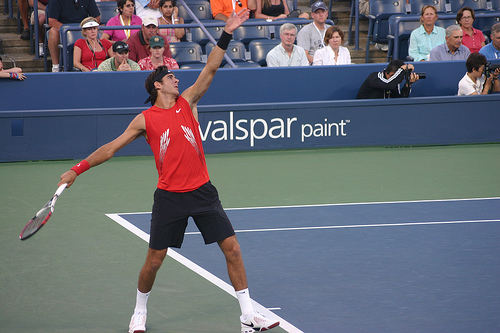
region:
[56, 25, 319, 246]
this is a tennis match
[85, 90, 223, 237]
the tank top is red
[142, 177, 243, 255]
the shorts are black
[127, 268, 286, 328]
the shoes are white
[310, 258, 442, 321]
the court is blue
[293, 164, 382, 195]
the court is green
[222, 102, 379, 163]
this is an advertisement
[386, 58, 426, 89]
a man with a camera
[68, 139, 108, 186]
a red arm band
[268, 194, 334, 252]
white lines on the court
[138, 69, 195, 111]
a man wearing a hat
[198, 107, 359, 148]
letters on the wall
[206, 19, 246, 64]
a black arm band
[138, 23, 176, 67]
a woman wearing a hat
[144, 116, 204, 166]
a picture on the shirt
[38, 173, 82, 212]
a handle on the racket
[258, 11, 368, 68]
people watching the game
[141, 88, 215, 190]
man wearing red tank top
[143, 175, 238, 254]
black shorts on tennis player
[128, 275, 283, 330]
white socks and white tennis shoes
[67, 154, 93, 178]
red sweatbands on man's wrists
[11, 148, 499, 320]
blue and green tennis court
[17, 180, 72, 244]
white black and red tennis racket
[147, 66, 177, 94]
black sweatband on man's head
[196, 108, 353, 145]
white letters showing sponsor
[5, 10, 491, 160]
blue stands filled with spectators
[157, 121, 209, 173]
white Nike design onb famous tennis player Rafael Nadal's shirt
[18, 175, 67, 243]
man is holding a tennis racket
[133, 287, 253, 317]
man is wearing white socks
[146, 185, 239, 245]
man is wearing black shorts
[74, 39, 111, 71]
woman is wearing a red shirt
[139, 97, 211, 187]
man is wearing a red shirt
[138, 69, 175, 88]
man is wearing a black head band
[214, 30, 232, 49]
man wearing a black wrist band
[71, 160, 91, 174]
man is wearing a red wrist band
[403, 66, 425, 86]
man holding a black camera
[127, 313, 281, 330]
man is wearing white tennis shoes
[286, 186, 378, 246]
a white line on the ground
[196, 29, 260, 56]
a black arm band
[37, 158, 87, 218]
a white handle on a racket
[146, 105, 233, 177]
picture on a shirt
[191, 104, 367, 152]
a name on the wall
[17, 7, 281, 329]
the man playing tennis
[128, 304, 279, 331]
the shoes on the man's feet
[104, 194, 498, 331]
the white lines on the court